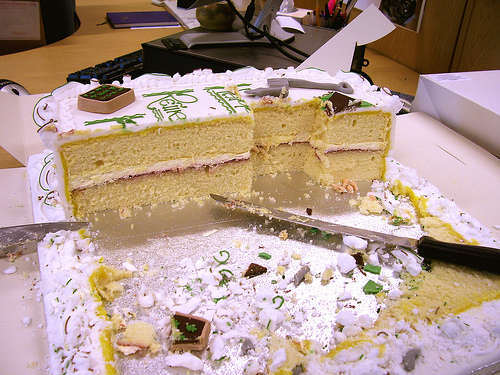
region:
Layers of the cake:
[56, 123, 394, 216]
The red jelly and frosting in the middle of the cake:
[73, 143, 252, 205]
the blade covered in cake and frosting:
[209, 185, 419, 256]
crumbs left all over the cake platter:
[171, 253, 399, 360]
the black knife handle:
[418, 233, 498, 268]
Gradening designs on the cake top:
[67, 65, 385, 115]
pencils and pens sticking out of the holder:
[303, 0, 360, 32]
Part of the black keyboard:
[71, 44, 141, 82]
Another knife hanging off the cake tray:
[1, 219, 101, 256]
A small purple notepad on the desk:
[97, 7, 181, 32]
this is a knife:
[201, 167, 461, 267]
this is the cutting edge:
[312, 216, 344, 231]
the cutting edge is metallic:
[295, 202, 332, 246]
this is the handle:
[434, 229, 498, 275]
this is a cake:
[187, 97, 239, 176]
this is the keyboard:
[90, 50, 137, 82]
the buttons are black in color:
[108, 51, 130, 64]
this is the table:
[26, 51, 55, 73]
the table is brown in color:
[35, 52, 55, 78]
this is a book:
[106, 6, 146, 24]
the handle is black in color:
[427, 242, 474, 263]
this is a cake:
[62, 98, 269, 142]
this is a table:
[36, 40, 63, 84]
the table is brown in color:
[19, 40, 79, 95]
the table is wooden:
[37, 50, 48, 74]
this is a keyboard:
[91, 60, 124, 71]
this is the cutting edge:
[243, 197, 333, 239]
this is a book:
[111, 15, 165, 29]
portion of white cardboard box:
[3, 327, 36, 353]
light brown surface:
[63, 41, 120, 60]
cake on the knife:
[227, 193, 282, 223]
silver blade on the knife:
[212, 193, 432, 272]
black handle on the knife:
[416, 233, 495, 273]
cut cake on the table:
[52, 115, 370, 239]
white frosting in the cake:
[95, 160, 210, 177]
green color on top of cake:
[73, 81, 175, 110]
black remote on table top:
[76, 50, 137, 73]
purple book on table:
[98, 7, 185, 34]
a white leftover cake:
[37, 62, 385, 169]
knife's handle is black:
[405, 233, 476, 292]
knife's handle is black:
[419, 240, 494, 275]